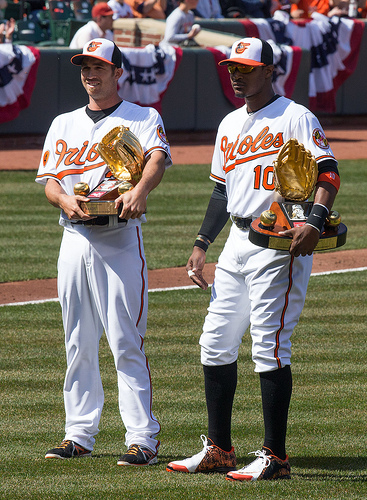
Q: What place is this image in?
A: It is at the field.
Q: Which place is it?
A: It is a field.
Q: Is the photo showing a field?
A: Yes, it is showing a field.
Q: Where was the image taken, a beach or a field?
A: It was taken at a field.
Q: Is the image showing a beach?
A: No, the picture is showing a field.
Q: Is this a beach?
A: No, it is a field.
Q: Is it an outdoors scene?
A: Yes, it is outdoors.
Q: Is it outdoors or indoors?
A: It is outdoors.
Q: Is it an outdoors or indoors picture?
A: It is outdoors.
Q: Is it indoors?
A: No, it is outdoors.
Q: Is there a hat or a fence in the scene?
A: Yes, there is a hat.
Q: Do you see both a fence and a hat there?
A: Yes, there are both a hat and a fence.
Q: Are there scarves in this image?
A: No, there are no scarves.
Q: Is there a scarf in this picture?
A: No, there are no scarves.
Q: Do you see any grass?
A: Yes, there is grass.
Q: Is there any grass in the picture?
A: Yes, there is grass.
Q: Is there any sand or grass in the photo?
A: Yes, there is grass.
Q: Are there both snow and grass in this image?
A: No, there is grass but no snow.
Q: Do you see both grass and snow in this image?
A: No, there is grass but no snow.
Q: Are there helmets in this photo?
A: No, there are no helmets.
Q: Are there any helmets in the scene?
A: No, there are no helmets.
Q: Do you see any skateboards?
A: No, there are no skateboards.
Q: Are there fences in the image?
A: Yes, there is a fence.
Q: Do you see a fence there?
A: Yes, there is a fence.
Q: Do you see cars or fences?
A: Yes, there is a fence.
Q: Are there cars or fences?
A: Yes, there is a fence.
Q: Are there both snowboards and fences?
A: No, there is a fence but no snowboards.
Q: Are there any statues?
A: No, there are no statues.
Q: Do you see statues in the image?
A: No, there are no statues.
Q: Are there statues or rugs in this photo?
A: No, there are no statues or rugs.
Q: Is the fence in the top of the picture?
A: Yes, the fence is in the top of the image.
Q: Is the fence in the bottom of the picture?
A: No, the fence is in the top of the image.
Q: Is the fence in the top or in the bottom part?
A: The fence is in the top of the image.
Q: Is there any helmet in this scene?
A: No, there are no helmets.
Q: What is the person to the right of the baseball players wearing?
A: The man is wearing a hat.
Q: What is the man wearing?
A: The man is wearing a hat.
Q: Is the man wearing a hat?
A: Yes, the man is wearing a hat.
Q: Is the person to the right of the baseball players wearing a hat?
A: Yes, the man is wearing a hat.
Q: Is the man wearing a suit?
A: No, the man is wearing a hat.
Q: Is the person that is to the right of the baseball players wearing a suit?
A: No, the man is wearing a hat.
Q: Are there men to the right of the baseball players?
A: Yes, there is a man to the right of the baseball players.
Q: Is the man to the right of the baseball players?
A: Yes, the man is to the right of the baseball players.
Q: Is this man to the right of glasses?
A: No, the man is to the right of the baseball players.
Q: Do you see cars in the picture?
A: No, there are no cars.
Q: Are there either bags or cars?
A: No, there are no cars or bags.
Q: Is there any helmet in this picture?
A: No, there are no helmets.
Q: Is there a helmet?
A: No, there are no helmets.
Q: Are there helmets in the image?
A: No, there are no helmets.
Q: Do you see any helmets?
A: No, there are no helmets.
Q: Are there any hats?
A: Yes, there is a hat.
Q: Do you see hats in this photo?
A: Yes, there is a hat.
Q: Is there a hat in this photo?
A: Yes, there is a hat.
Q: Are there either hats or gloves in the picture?
A: Yes, there is a hat.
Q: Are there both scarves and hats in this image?
A: No, there is a hat but no scarves.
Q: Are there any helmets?
A: No, there are no helmets.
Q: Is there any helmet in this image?
A: No, there are no helmets.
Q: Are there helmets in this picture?
A: No, there are no helmets.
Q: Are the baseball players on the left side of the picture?
A: Yes, the baseball players are on the left of the image.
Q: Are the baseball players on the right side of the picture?
A: No, the baseball players are on the left of the image.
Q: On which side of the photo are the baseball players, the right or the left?
A: The baseball players are on the left of the image.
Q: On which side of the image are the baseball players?
A: The baseball players are on the left of the image.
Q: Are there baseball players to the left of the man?
A: Yes, there are baseball players to the left of the man.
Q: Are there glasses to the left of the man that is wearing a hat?
A: No, there are baseball players to the left of the man.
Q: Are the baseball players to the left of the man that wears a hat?
A: Yes, the baseball players are to the left of the man.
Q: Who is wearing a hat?
A: The baseball players are wearing a hat.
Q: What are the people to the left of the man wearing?
A: The baseball players are wearing a hat.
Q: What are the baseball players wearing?
A: The baseball players are wearing a hat.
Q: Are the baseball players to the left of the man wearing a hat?
A: Yes, the baseball players are wearing a hat.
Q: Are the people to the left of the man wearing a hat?
A: Yes, the baseball players are wearing a hat.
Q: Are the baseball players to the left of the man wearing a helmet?
A: No, the baseball players are wearing a hat.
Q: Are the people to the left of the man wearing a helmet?
A: No, the baseball players are wearing a hat.